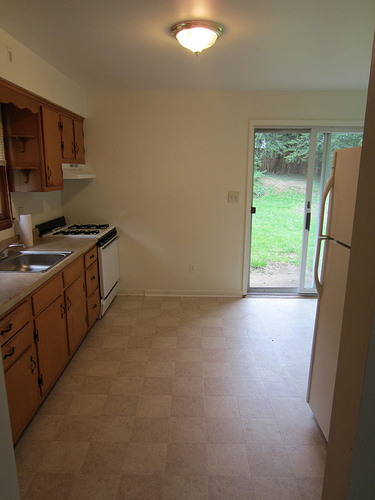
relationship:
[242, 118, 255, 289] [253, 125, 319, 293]
white frame on door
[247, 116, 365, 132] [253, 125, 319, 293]
white frame on door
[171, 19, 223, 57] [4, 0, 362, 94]
light on ceiling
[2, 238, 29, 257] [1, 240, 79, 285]
faucet attached to sink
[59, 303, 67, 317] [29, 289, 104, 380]
handle attached to cabinet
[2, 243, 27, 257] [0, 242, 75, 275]
faucet over sink